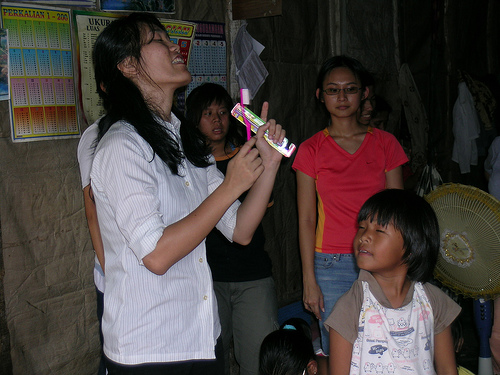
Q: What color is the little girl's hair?
A: Black.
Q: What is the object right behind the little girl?
A: Fan.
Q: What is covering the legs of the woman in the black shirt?
A: Pants.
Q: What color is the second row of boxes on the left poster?
A: Blue.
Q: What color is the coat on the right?
A: White.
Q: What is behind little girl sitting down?
A: A fan.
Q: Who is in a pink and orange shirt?
A: Girl with glasses.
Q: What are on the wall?
A: Signs.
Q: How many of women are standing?
A: 4.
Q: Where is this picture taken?
A: Classroom.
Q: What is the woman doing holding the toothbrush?
A: Giving a presentation.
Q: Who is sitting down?
A: Little girl in tshirt.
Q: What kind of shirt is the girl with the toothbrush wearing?
A: A button up shirt.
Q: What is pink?
A: Toothbrush.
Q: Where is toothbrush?
A: Woman's hand.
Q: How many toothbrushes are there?
A: 1.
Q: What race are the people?
A: Asian.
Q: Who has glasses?
A: Girl in red.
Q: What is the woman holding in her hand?
A: A toothbrush.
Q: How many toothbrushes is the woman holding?
A: One.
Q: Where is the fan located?
A: Behind the girl.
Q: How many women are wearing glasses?
A: One.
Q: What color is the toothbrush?
A: Pink.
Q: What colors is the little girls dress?
A: White, pink & blue.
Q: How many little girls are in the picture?
A: One.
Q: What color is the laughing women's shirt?
A: White.